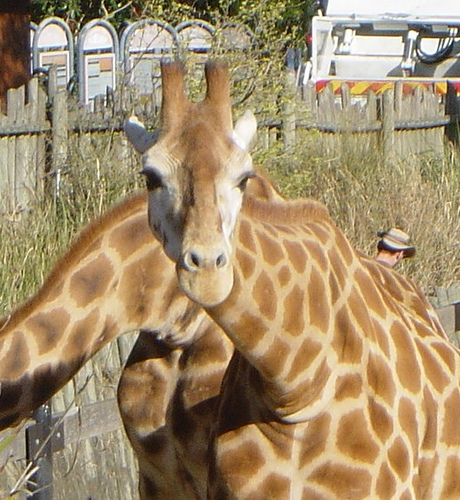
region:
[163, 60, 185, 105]
A horn in a giraffe's head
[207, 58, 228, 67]
A tuft of black hairs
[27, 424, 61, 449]
A hinge on the door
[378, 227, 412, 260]
A person's head behind a giraffe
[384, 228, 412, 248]
A hat on the head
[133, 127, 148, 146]
Shadow on a giraffe's ear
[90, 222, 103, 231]
Hair bristles on the neck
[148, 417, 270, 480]
The abdomens of two giraffes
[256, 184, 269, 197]
The back of a giraffe behind another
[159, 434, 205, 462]
Shadow cast by one giraffe on another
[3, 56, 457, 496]
two brown and tan giraffes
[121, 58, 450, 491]
giraffe looking at the camera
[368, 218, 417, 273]
a person wearing a tan and brown hat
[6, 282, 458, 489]
wooden fence in the background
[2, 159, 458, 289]
tall grass and weeds between fences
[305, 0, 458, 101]
large sized truck behind the fence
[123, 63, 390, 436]
giraffe has wrinkles on it's neck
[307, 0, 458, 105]
red and yellow reflectors on the back of a truck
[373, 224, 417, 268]
man looking downward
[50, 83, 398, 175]
three wooden posts holding wooden fence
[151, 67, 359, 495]
Large giraffe by fence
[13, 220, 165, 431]
Large giraffe by fence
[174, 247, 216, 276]
round nostril of giraffe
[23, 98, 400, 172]
wood fence in background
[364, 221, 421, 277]
man with hat behind giraffe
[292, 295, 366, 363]
yellow and brown spots on giraffe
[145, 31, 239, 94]
small horns on giraffe's head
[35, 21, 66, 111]
small portable toilet at zoo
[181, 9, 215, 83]
small portable toilet at zoo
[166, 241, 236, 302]
the giraffe has a nose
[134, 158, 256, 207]
the giraffe has eyes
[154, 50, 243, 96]
the giraffe has horns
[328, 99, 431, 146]
the fence is wooden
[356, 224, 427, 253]
the hat is tan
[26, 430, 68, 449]
the screws in the fence are silver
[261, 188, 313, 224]
the giraffe has a mane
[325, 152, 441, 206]
the vegitation is brown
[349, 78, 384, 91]
the stripes are red and yellow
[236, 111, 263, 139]
the giraffe has an ear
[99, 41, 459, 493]
giraffe looking at camera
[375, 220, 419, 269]
person behind the giraffes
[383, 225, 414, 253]
hat of person behind giraffes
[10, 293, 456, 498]
wood fencing behind giraffes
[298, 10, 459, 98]
trash truck behind background wood fence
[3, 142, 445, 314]
long grass growing along fenceline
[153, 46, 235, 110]
furry horns on giraffe's head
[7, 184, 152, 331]
brown mane on neck of second giraffe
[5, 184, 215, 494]
giraffe with it's neck bent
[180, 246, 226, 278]
nostrils of giraffe looking at camera